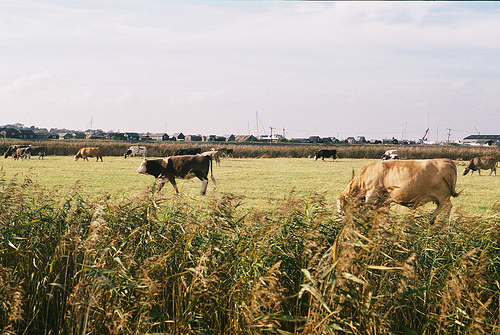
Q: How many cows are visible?
A: Eight.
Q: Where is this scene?
A: A farm.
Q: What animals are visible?
A: Cows.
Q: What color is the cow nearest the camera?
A: Brown.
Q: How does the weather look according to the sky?
A: Cloudy.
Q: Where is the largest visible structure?
A: Upper right hand corner.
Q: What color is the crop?
A: Green and tan.